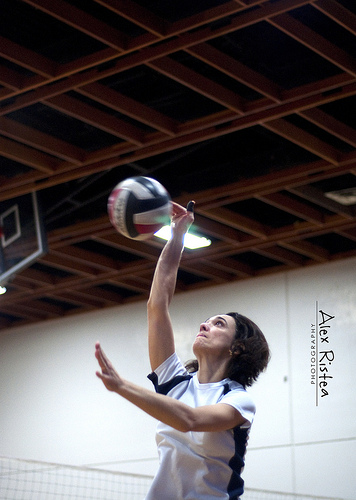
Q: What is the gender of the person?
A: Female.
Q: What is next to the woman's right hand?
A: Ball.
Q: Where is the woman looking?
A: Up.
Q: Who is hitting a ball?
A: A woman.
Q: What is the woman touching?
A: A volleyball.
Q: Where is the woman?
A: Inside a building.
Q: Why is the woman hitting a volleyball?
A: She is playing volleyball.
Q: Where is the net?
A: Behind the woman.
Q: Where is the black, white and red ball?
A: In the air.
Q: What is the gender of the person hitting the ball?
A: Female.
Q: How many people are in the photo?
A: One.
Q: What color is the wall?
A: White.